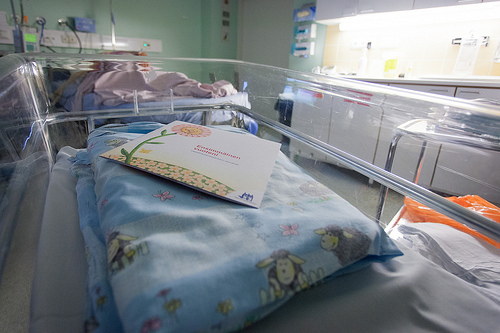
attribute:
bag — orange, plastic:
[405, 185, 494, 257]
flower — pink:
[119, 120, 210, 168]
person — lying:
[45, 53, 267, 125]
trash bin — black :
[268, 85, 301, 143]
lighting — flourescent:
[322, 2, 497, 42]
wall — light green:
[8, 5, 236, 115]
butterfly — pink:
[271, 217, 304, 242]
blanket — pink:
[83, 64, 248, 99]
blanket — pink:
[88, 64, 240, 101]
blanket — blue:
[76, 123, 388, 323]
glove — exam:
[170, 77, 203, 97]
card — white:
[95, 114, 282, 209]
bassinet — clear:
[3, 52, 498, 332]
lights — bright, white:
[315, 4, 496, 90]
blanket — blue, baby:
[257, 168, 349, 248]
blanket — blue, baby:
[73, 112, 408, 328]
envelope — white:
[121, 120, 267, 205]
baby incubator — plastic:
[5, 48, 493, 331]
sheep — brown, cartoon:
[250, 247, 313, 299]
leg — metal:
[375, 132, 403, 222]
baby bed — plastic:
[1, 100, 499, 331]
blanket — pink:
[81, 69, 228, 96]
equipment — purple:
[73, 15, 96, 36]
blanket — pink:
[83, 69, 240, 105]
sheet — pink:
[76, 66, 238, 106]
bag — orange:
[391, 165, 498, 255]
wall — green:
[172, 9, 197, 54]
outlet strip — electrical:
[0, 24, 164, 54]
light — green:
[128, 12, 189, 92]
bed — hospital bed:
[61, 57, 325, 326]